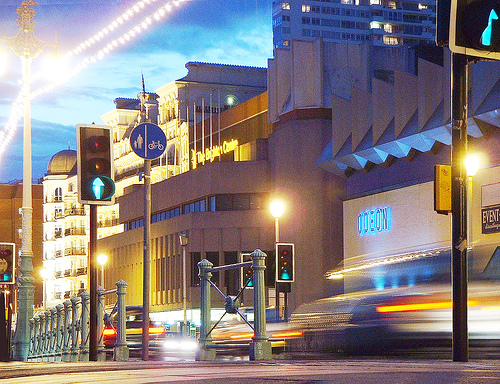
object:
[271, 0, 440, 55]
building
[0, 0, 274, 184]
sky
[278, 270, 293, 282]
light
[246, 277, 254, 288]
light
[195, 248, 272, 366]
fence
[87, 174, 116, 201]
light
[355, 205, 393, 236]
sign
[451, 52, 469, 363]
pole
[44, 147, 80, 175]
roof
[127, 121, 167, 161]
sign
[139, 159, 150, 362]
pole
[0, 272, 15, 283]
light